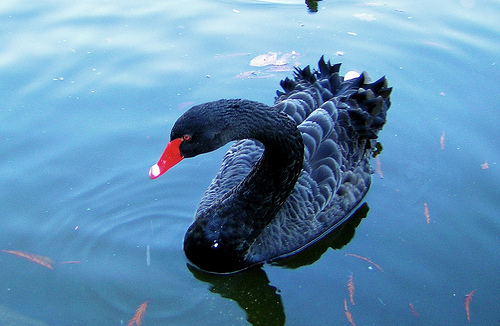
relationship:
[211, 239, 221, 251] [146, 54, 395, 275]
white debris on black bird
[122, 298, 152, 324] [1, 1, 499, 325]
orange fish in water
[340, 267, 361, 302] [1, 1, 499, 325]
orange fish in water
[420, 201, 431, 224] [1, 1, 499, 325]
orange fish in water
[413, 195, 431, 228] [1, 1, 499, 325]
orange fish in water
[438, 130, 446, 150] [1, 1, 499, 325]
fishes in water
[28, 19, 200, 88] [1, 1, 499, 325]
clouds reflection on water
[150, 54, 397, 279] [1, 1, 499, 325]
black bird in water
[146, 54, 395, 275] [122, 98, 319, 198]
black bird has head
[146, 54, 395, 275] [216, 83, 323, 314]
black bird has neck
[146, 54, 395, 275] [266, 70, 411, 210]
black bird has feathers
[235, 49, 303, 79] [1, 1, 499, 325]
leaf in water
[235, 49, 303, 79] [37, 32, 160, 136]
leaf in water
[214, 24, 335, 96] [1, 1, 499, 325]
leaf in water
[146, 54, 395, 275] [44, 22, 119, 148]
black bird on lake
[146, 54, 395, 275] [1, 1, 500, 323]
black bird on lake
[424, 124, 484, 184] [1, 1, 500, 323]
fishes on lake